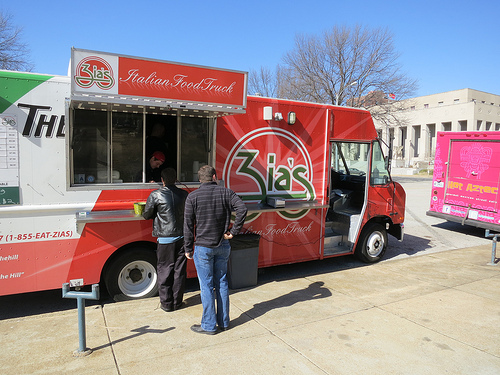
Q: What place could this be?
A: It is a sidewalk.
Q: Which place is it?
A: It is a sidewalk.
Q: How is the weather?
A: It is clear.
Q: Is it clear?
A: Yes, it is clear.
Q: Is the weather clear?
A: Yes, it is clear.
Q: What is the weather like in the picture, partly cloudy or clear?
A: It is clear.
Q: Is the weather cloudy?
A: No, it is clear.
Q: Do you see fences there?
A: No, there are no fences.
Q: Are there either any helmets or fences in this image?
A: No, there are no fences or helmets.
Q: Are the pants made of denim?
A: Yes, the pants are made of denim.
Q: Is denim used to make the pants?
A: Yes, the pants are made of denim.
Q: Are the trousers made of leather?
A: No, the trousers are made of denim.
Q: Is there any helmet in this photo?
A: No, there are no helmets.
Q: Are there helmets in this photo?
A: No, there are no helmets.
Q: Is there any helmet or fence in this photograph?
A: No, there are no helmets or fences.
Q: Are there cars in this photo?
A: No, there are no cars.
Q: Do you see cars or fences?
A: No, there are no cars or fences.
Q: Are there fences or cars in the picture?
A: No, there are no cars or fences.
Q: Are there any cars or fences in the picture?
A: No, there are no cars or fences.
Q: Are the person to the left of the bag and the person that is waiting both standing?
A: Yes, both the person and the person are standing.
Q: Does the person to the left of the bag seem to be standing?
A: Yes, the person is standing.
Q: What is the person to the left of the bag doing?
A: The person is standing.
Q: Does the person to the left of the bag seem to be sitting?
A: No, the person is standing.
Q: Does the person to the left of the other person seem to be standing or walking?
A: The person is standing.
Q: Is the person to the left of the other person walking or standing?
A: The person is standing.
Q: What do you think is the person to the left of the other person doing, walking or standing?
A: The person is standing.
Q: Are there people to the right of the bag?
A: No, the person is to the left of the bag.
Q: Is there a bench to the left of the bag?
A: No, there is a person to the left of the bag.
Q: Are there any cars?
A: No, there are no cars.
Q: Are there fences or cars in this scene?
A: No, there are no cars or fences.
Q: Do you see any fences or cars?
A: No, there are no cars or fences.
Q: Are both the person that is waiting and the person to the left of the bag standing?
A: Yes, both the person and the person are standing.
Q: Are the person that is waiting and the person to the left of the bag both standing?
A: Yes, both the person and the person are standing.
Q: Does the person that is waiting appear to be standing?
A: Yes, the person is standing.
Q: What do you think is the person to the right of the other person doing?
A: The person is standing.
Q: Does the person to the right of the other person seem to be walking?
A: No, the person is standing.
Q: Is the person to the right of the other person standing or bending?
A: The person is standing.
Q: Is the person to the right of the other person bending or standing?
A: The person is standing.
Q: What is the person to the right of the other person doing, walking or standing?
A: The person is standing.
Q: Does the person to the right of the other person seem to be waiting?
A: Yes, the person is waiting.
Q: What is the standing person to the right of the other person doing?
A: The person is waiting.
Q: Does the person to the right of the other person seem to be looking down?
A: No, the person is waiting.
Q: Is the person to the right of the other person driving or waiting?
A: The person is waiting.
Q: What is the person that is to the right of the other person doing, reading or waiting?
A: The person is waiting.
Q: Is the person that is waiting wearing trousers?
A: Yes, the person is wearing trousers.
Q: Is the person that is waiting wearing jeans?
A: No, the person is wearing trousers.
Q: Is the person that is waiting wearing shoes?
A: Yes, the person is wearing shoes.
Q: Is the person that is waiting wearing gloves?
A: No, the person is wearing shoes.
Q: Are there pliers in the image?
A: No, there are no pliers.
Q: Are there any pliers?
A: No, there are no pliers.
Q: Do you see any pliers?
A: No, there are no pliers.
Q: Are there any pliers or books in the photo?
A: No, there are no pliers or books.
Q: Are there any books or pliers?
A: No, there are no pliers or books.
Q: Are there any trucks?
A: Yes, there is a truck.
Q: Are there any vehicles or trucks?
A: Yes, there is a truck.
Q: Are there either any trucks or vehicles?
A: Yes, there is a truck.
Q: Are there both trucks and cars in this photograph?
A: No, there is a truck but no cars.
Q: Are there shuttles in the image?
A: No, there are no shuttles.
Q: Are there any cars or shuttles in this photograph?
A: No, there are no shuttles or cars.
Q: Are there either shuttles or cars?
A: No, there are no shuttles or cars.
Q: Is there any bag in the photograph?
A: Yes, there is a bag.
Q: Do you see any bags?
A: Yes, there is a bag.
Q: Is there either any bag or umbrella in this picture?
A: Yes, there is a bag.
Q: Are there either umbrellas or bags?
A: Yes, there is a bag.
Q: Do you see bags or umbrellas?
A: Yes, there is a bag.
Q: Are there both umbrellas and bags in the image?
A: No, there is a bag but no umbrellas.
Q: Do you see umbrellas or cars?
A: No, there are no cars or umbrellas.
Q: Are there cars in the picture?
A: No, there are no cars.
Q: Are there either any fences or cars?
A: No, there are no cars or fences.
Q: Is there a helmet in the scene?
A: No, there are no helmets.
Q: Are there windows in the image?
A: Yes, there is a window.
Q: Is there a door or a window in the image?
A: Yes, there is a window.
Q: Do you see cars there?
A: No, there are no cars.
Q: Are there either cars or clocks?
A: No, there are no cars or clocks.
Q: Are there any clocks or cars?
A: No, there are no cars or clocks.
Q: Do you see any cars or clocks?
A: No, there are no cars or clocks.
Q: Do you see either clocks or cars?
A: No, there are no cars or clocks.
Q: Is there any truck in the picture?
A: Yes, there is a truck.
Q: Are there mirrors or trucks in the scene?
A: Yes, there is a truck.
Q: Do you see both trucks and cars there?
A: No, there is a truck but no cars.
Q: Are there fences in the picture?
A: No, there are no fences.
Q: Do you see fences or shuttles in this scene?
A: No, there are no fences or shuttles.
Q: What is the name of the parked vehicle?
A: The vehicle is a truck.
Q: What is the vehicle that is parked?
A: The vehicle is a truck.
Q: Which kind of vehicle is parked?
A: The vehicle is a truck.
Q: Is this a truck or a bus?
A: This is a truck.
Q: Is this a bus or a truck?
A: This is a truck.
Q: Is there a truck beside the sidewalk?
A: Yes, there is a truck beside the sidewalk.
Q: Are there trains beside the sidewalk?
A: No, there is a truck beside the sidewalk.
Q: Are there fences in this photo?
A: No, there are no fences.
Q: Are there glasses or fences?
A: No, there are no fences or glasses.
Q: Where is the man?
A: The man is in the truck.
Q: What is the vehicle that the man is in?
A: The vehicle is a truck.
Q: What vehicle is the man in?
A: The man is in the truck.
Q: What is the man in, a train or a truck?
A: The man is in a truck.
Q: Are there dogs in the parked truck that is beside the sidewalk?
A: No, there is a man in the truck.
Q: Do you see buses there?
A: No, there are no buses.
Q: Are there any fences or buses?
A: No, there are no buses or fences.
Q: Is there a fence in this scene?
A: No, there are no fences.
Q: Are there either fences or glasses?
A: No, there are no fences or glasses.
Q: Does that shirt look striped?
A: Yes, the shirt is striped.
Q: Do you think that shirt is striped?
A: Yes, the shirt is striped.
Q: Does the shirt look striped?
A: Yes, the shirt is striped.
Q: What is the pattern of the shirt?
A: The shirt is striped.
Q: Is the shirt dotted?
A: No, the shirt is striped.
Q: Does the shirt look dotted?
A: No, the shirt is striped.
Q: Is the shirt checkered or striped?
A: The shirt is striped.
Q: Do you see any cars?
A: No, there are no cars.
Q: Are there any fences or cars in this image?
A: No, there are no cars or fences.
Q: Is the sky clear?
A: Yes, the sky is clear.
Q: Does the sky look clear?
A: Yes, the sky is clear.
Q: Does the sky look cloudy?
A: No, the sky is clear.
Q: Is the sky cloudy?
A: No, the sky is clear.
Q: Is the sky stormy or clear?
A: The sky is clear.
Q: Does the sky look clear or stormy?
A: The sky is clear.